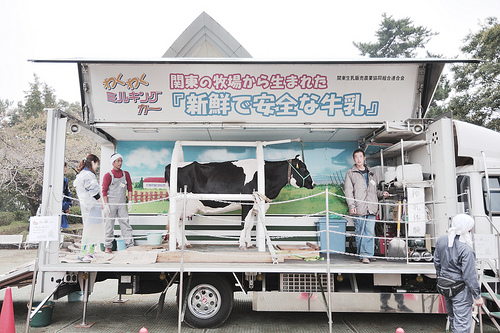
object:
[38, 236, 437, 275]
platform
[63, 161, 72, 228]
person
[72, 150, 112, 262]
person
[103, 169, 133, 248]
coveralls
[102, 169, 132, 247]
overalls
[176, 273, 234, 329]
wheel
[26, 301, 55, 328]
bucket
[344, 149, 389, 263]
guy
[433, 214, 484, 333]
guy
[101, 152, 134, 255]
guy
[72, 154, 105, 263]
guy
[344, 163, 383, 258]
overall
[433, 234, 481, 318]
overall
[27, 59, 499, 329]
trailer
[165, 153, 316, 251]
cow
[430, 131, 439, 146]
ground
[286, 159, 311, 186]
green harness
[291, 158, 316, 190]
face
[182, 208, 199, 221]
utters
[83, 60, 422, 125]
sign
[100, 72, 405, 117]
colorful words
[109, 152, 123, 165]
headband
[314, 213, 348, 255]
trash can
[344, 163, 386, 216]
coat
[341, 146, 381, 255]
mixer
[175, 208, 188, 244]
legs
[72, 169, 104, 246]
jacket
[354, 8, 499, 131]
tree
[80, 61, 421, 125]
asian writing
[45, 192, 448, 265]
chain link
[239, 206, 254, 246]
legs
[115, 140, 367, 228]
scenary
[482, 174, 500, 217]
window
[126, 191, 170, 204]
fence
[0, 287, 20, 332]
cone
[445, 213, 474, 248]
t-shirt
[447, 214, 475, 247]
head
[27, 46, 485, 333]
rig